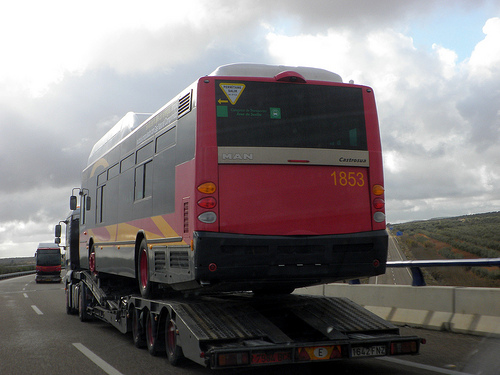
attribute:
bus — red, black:
[70, 62, 389, 299]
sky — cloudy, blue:
[0, 1, 498, 259]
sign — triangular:
[217, 82, 246, 105]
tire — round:
[136, 239, 151, 298]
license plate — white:
[351, 344, 387, 358]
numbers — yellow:
[329, 171, 366, 188]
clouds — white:
[0, 1, 499, 242]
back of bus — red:
[194, 70, 387, 236]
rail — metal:
[386, 258, 498, 267]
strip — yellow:
[86, 214, 189, 249]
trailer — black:
[55, 205, 426, 371]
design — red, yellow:
[88, 159, 190, 246]